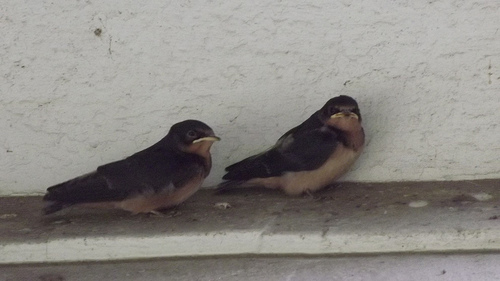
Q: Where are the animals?
A: On a ledge.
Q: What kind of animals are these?
A: Birds.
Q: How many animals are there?
A: Two.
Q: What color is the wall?
A: White.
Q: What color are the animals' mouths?
A: Yellow.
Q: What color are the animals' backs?
A: Brown.